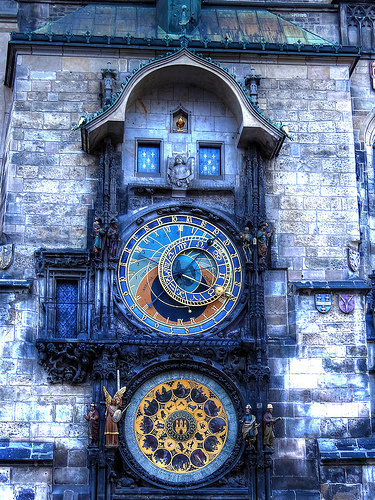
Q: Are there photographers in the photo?
A: No, there are no photographers.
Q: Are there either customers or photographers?
A: No, there are no photographers or customers.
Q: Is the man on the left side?
A: Yes, the man is on the left of the image.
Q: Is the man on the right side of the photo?
A: No, the man is on the left of the image.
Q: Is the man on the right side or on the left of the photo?
A: The man is on the left of the image.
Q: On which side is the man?
A: The man is on the left of the image.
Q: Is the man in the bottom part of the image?
A: Yes, the man is in the bottom of the image.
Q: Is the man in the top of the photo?
A: No, the man is in the bottom of the image.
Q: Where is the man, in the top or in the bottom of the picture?
A: The man is in the bottom of the image.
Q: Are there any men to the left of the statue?
A: Yes, there is a man to the left of the statue.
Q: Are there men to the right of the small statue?
A: No, the man is to the left of the statue.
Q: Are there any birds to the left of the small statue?
A: No, there is a man to the left of the statue.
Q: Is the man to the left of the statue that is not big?
A: Yes, the man is to the left of the statue.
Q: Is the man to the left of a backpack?
A: No, the man is to the left of the statue.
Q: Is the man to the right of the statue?
A: No, the man is to the left of the statue.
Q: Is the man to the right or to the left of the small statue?
A: The man is to the left of the statue.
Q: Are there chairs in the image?
A: No, there are no chairs.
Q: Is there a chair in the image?
A: No, there are no chairs.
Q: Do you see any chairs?
A: No, there are no chairs.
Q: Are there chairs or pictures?
A: No, there are no chairs or pictures.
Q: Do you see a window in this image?
A: Yes, there is a window.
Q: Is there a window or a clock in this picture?
A: Yes, there is a window.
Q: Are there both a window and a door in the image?
A: No, there is a window but no doors.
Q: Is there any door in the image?
A: No, there are no doors.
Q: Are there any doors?
A: No, there are no doors.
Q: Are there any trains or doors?
A: No, there are no doors or trains.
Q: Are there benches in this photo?
A: No, there are no benches.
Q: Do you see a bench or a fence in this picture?
A: No, there are no benches or fences.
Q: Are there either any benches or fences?
A: No, there are no benches or fences.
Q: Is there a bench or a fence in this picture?
A: No, there are no benches or fences.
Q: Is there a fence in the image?
A: No, there are no fences.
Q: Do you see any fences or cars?
A: No, there are no fences or cars.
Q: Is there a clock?
A: Yes, there is a clock.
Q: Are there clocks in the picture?
A: Yes, there is a clock.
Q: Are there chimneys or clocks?
A: Yes, there is a clock.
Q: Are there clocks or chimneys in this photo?
A: Yes, there is a clock.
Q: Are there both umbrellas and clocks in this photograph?
A: No, there is a clock but no umbrellas.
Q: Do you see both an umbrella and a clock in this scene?
A: No, there is a clock but no umbrellas.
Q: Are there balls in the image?
A: No, there are no balls.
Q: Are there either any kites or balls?
A: No, there are no balls or kites.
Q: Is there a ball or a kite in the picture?
A: No, there are no balls or kites.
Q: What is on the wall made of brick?
A: The clock is on the wall.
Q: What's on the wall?
A: The clock is on the wall.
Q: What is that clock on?
A: The clock is on the wall.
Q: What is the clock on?
A: The clock is on the wall.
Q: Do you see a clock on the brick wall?
A: Yes, there is a clock on the wall.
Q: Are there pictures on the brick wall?
A: No, there is a clock on the wall.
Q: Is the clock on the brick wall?
A: Yes, the clock is on the wall.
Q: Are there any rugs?
A: No, there are no rugs.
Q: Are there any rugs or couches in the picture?
A: No, there are no rugs or couches.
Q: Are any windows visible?
A: Yes, there is a window.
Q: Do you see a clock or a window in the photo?
A: Yes, there is a window.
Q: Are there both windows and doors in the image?
A: No, there is a window but no doors.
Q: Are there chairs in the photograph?
A: No, there are no chairs.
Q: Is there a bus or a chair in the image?
A: No, there are no chairs or buses.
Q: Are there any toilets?
A: No, there are no toilets.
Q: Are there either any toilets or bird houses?
A: No, there are no toilets or bird houses.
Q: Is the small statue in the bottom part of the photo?
A: Yes, the statue is in the bottom of the image.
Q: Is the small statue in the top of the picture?
A: No, the statue is in the bottom of the image.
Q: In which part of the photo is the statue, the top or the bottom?
A: The statue is in the bottom of the image.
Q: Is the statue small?
A: Yes, the statue is small.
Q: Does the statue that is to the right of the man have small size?
A: Yes, the statue is small.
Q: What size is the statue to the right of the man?
A: The statue is small.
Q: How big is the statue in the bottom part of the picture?
A: The statue is small.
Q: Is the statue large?
A: No, the statue is small.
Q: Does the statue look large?
A: No, the statue is small.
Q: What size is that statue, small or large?
A: The statue is small.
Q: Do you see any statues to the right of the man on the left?
A: Yes, there is a statue to the right of the man.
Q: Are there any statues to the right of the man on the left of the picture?
A: Yes, there is a statue to the right of the man.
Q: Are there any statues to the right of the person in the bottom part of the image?
A: Yes, there is a statue to the right of the man.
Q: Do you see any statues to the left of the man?
A: No, the statue is to the right of the man.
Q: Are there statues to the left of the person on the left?
A: No, the statue is to the right of the man.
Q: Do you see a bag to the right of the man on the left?
A: No, there is a statue to the right of the man.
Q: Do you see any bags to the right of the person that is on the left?
A: No, there is a statue to the right of the man.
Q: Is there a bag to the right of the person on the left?
A: No, there is a statue to the right of the man.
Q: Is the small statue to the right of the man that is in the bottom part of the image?
A: Yes, the statue is to the right of the man.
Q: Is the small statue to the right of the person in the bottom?
A: Yes, the statue is to the right of the man.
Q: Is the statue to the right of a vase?
A: No, the statue is to the right of the man.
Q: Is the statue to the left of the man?
A: No, the statue is to the right of the man.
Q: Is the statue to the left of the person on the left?
A: No, the statue is to the right of the man.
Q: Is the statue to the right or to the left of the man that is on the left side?
A: The statue is to the right of the man.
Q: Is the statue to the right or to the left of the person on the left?
A: The statue is to the right of the man.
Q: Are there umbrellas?
A: No, there are no umbrellas.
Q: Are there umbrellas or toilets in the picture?
A: No, there are no umbrellas or toilets.